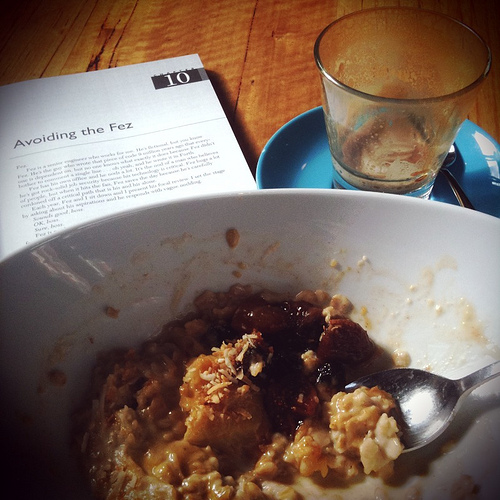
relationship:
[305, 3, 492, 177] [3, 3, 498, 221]
glass on table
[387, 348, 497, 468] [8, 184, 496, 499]
spoon in a bowl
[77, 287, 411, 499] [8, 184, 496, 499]
porridge in bowl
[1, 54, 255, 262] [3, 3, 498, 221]
paper on table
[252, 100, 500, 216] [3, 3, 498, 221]
plate on table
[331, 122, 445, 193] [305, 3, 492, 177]
water in a glass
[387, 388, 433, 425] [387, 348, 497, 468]
light reflecting on a spoon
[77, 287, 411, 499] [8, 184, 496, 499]
porridge in a bowl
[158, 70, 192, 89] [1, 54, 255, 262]
number 10 on a paper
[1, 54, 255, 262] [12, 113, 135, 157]
paper says avoiding the fez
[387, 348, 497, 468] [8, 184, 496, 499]
spoon in bowl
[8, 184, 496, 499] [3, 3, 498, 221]
bowl on table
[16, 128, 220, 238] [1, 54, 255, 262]
text on paper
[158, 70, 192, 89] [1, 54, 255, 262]
number 10 on paper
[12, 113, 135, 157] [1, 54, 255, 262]
avoiding the fez on paper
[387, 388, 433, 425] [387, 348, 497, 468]
light reflecting on spoon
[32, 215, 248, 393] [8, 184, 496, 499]
crumbs on side of bowl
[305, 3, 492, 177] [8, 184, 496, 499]
glass next to bowl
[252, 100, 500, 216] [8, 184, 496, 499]
plate next to bowl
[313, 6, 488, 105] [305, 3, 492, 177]
lip of glass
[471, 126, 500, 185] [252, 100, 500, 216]
reflection on plate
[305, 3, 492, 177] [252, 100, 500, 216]
glass on plate